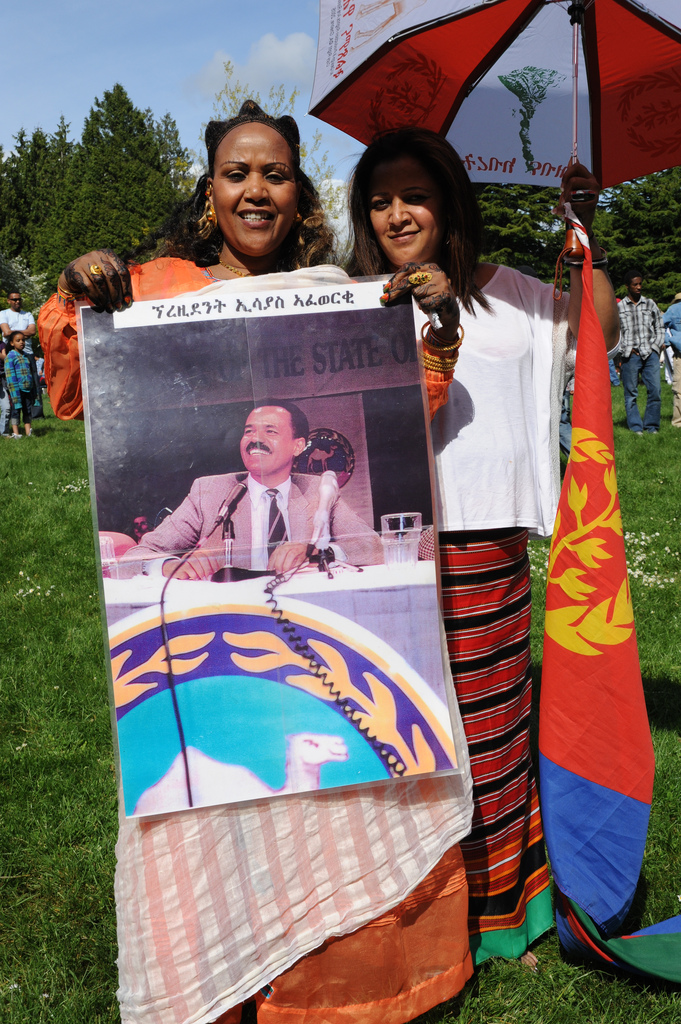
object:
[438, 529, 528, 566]
stripe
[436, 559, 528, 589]
stripe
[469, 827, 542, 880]
stripes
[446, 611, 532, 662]
stripe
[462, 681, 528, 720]
stripe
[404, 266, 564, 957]
dress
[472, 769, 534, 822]
stripe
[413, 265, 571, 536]
shirt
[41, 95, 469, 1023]
woman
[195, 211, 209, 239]
earing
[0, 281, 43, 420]
father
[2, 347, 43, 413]
sweater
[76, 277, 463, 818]
picture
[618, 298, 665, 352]
shirt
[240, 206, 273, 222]
teeth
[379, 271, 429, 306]
fingers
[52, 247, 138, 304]
hand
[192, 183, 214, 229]
ear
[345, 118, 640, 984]
woman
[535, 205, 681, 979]
flag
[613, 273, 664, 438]
man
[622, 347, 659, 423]
jeans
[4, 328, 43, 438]
child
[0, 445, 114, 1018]
grass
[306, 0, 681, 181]
umbrella